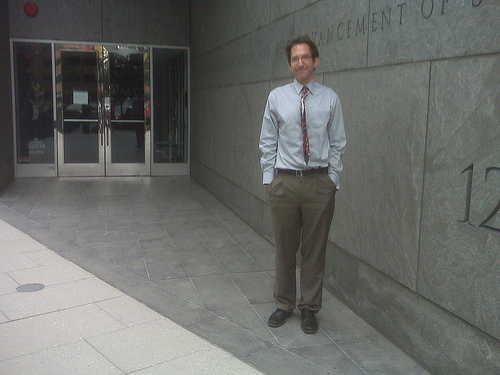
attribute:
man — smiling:
[260, 36, 339, 340]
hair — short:
[290, 38, 319, 57]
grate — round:
[13, 278, 58, 295]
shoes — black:
[266, 296, 320, 338]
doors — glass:
[42, 53, 236, 195]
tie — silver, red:
[283, 97, 325, 181]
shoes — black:
[256, 272, 338, 354]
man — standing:
[273, 37, 351, 320]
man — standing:
[275, 75, 372, 333]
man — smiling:
[223, 9, 435, 367]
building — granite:
[342, 4, 497, 369]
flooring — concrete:
[4, 177, 440, 373]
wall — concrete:
[188, 0, 498, 372]